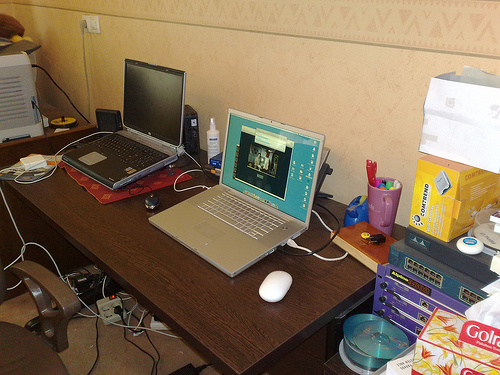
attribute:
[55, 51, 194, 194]
laptop — gray, black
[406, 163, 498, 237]
box — bright yellow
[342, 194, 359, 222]
tape dispenser — blue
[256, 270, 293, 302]
mouse — white, little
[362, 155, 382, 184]
scissors — red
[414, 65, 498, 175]
box — white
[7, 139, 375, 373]
wooden table — large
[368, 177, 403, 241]
cup — pink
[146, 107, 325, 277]
laptop — silver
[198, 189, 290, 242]
keyboard — blue, silver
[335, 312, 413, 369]
cds — stack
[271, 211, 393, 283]
jack — electric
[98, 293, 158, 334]
plugs — white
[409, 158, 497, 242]
box — small, yellow, cardboard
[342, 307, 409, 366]
stack — cd's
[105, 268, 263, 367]
desk top — dark, wooden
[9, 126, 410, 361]
table — dark, wood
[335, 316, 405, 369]
compact disc — green, grey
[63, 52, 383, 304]
computers — pair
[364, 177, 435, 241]
cup — pink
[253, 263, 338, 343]
cordless mouse — white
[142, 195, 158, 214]
mouse — little, black